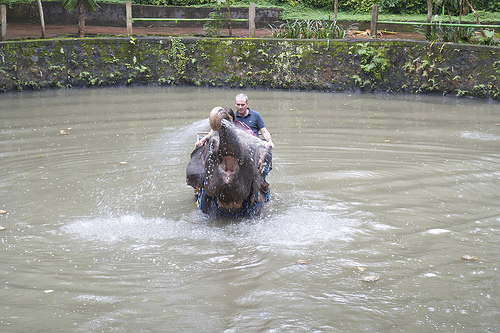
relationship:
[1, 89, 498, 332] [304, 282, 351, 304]
water has ripples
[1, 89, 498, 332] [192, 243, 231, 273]
water has ripples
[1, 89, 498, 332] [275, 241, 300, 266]
water has ripples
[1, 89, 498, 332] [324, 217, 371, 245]
water has ripples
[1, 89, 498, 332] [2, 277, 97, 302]
water has ripples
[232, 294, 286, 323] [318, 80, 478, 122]
ripples in water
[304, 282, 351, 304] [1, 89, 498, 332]
ripples in water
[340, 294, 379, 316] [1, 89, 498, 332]
ripples in water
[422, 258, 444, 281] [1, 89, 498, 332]
ripples in water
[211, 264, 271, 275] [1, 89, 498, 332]
ripples in water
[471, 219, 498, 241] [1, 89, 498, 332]
ripples in water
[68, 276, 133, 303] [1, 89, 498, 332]
ripples in water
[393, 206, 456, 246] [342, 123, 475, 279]
ripples in water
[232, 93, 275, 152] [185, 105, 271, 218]
man on elephant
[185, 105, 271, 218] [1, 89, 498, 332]
elephant in water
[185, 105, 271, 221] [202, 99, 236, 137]
elephant has trunk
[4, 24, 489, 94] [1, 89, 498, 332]
concrete edge near water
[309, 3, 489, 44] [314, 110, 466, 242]
grass beyond water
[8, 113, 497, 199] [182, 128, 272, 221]
ripples emitting from elephant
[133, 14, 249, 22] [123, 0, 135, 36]
rope stretched across pole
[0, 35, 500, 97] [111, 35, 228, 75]
short wall growing grass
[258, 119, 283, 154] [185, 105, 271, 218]
arm on elephant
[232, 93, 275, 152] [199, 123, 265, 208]
man sits on elephant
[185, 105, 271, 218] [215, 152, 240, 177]
elephant opens up mouth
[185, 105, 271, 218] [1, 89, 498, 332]
elephant sprays water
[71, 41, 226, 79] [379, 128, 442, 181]
plants cover ground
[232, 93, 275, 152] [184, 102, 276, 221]
man sits on elephant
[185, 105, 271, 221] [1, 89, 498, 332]
elephant spraying water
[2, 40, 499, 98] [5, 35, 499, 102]
dirt on bank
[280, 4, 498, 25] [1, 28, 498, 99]
grass on hill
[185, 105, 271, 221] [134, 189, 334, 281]
elephant makes waves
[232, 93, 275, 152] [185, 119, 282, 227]
man on elephant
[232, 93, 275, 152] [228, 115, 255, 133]
man in shirt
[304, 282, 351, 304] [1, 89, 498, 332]
ripples are in water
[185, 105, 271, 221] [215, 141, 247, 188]
elephant has mouth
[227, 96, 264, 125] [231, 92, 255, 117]
man has head